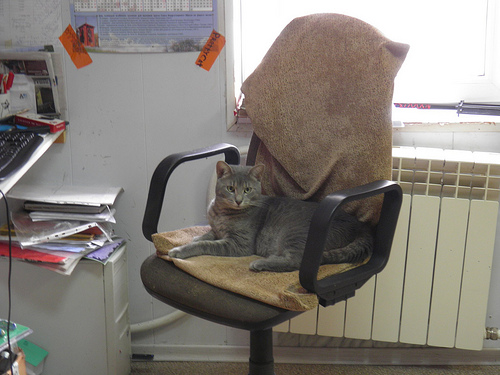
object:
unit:
[0, 241, 133, 375]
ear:
[216, 160, 233, 178]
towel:
[240, 13, 410, 228]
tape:
[58, 24, 94, 70]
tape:
[194, 29, 225, 72]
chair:
[139, 12, 403, 375]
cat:
[168, 161, 373, 271]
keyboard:
[0, 128, 44, 178]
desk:
[0, 129, 66, 202]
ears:
[248, 165, 264, 178]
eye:
[244, 188, 252, 193]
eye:
[227, 186, 235, 192]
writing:
[197, 32, 221, 67]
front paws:
[168, 245, 188, 259]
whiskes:
[250, 199, 275, 212]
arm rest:
[142, 142, 242, 242]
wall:
[100, 73, 192, 139]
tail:
[320, 232, 374, 264]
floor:
[298, 364, 497, 373]